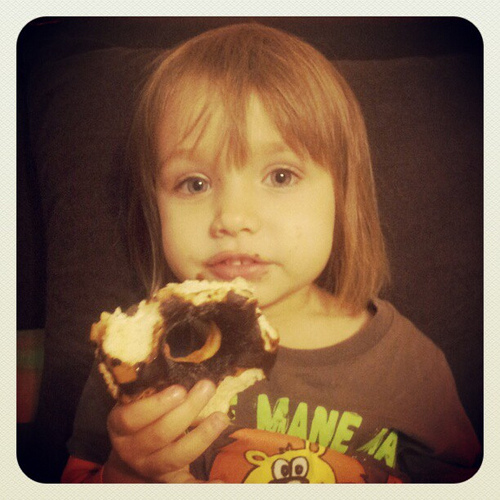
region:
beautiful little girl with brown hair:
[86, 21, 398, 311]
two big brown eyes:
[126, 122, 325, 218]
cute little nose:
[150, 177, 327, 247]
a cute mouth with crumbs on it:
[137, 223, 347, 305]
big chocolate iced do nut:
[56, 269, 315, 437]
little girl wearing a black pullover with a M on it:
[57, 299, 425, 474]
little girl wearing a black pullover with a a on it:
[223, 380, 429, 460]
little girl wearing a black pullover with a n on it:
[213, 377, 423, 459]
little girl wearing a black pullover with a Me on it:
[217, 368, 425, 465]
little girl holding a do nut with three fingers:
[58, 331, 351, 476]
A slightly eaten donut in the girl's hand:
[85, 285, 279, 410]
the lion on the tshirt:
[208, 415, 368, 484]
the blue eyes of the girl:
[161, 157, 306, 189]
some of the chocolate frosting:
[198, 290, 268, 368]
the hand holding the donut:
[112, 387, 228, 487]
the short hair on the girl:
[125, 22, 403, 329]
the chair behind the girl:
[36, 45, 488, 443]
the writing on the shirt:
[253, 395, 401, 458]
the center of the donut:
[169, 309, 211, 364]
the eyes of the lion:
[273, 452, 304, 478]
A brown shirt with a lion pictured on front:
[74, 285, 448, 478]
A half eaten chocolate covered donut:
[97, 283, 291, 426]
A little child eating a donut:
[118, 23, 383, 311]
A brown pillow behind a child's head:
[25, 53, 454, 339]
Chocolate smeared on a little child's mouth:
[177, 245, 286, 299]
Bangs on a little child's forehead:
[131, 50, 351, 167]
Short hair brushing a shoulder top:
[275, 185, 395, 347]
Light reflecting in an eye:
[260, 160, 295, 185]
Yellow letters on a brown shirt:
[251, 380, 406, 461]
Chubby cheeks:
[149, 212, 340, 289]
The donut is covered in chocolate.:
[65, 207, 316, 457]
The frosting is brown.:
[148, 285, 274, 360]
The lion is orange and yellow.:
[211, 386, 388, 498]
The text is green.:
[233, 369, 399, 464]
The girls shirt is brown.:
[96, 257, 458, 492]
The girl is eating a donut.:
[82, 144, 337, 481]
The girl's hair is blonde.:
[95, 33, 384, 323]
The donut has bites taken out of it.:
[53, 221, 260, 412]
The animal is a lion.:
[185, 381, 350, 498]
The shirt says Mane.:
[252, 368, 394, 464]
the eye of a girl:
[171, 167, 216, 201]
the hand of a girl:
[99, 370, 248, 482]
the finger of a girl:
[104, 385, 186, 437]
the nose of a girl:
[205, 177, 265, 250]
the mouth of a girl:
[197, 244, 291, 282]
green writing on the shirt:
[225, 391, 416, 471]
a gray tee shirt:
[59, 282, 479, 477]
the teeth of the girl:
[224, 254, 256, 269]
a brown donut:
[81, 277, 285, 404]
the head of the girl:
[134, 20, 384, 313]